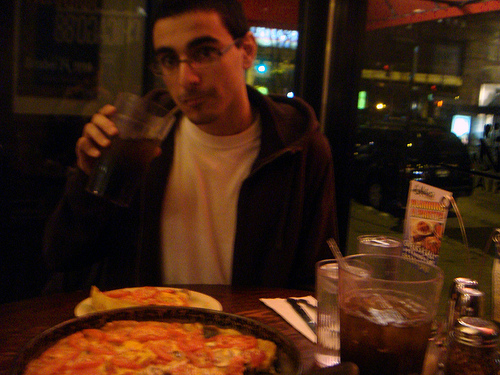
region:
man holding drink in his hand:
[59, 82, 210, 204]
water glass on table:
[300, 248, 355, 358]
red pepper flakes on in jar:
[442, 313, 498, 365]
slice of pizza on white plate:
[68, 279, 224, 311]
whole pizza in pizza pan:
[9, 313, 263, 374]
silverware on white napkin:
[275, 288, 313, 327]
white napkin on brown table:
[252, 286, 334, 342]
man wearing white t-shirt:
[163, 83, 262, 266]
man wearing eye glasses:
[132, 35, 296, 69]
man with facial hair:
[160, 60, 257, 123]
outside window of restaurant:
[356, 2, 498, 223]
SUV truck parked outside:
[354, 120, 473, 207]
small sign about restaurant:
[401, 179, 451, 259]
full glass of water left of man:
[358, 235, 405, 255]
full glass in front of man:
[314, 259, 357, 364]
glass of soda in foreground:
[336, 254, 444, 374]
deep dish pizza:
[8, 306, 365, 372]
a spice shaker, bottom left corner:
[450, 320, 497, 370]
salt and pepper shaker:
[449, 272, 486, 320]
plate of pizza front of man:
[76, 283, 223, 319]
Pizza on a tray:
[23, 311, 287, 371]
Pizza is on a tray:
[20, 315, 282, 372]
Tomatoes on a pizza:
[19, 311, 286, 373]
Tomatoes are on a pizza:
[20, 307, 291, 372]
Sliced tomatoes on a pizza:
[20, 314, 283, 373]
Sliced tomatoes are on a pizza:
[20, 317, 285, 373]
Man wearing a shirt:
[151, 105, 268, 283]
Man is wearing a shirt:
[153, 97, 264, 290]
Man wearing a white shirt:
[155, 93, 262, 290]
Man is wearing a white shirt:
[150, 104, 268, 291]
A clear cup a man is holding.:
[85, 96, 176, 210]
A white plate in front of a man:
[74, 284, 220, 317]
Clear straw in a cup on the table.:
[327, 239, 364, 306]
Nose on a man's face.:
[176, 53, 198, 89]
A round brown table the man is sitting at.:
[1, 284, 318, 373]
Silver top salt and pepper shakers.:
[436, 274, 483, 364]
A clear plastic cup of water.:
[312, 259, 342, 366]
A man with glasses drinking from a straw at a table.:
[45, 12, 337, 287]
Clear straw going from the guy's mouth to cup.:
[166, 97, 188, 119]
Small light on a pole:
[378, 56, 395, 79]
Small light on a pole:
[430, 80, 439, 92]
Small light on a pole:
[430, 91, 445, 113]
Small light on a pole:
[368, 94, 388, 123]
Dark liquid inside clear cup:
[49, 58, 182, 248]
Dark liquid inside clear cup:
[329, 232, 436, 369]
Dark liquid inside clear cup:
[299, 246, 350, 374]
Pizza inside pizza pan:
[25, 319, 247, 374]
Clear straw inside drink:
[321, 227, 378, 294]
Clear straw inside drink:
[154, 101, 189, 146]